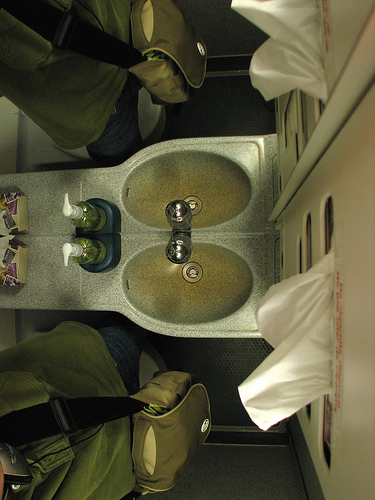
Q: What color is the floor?
A: Black.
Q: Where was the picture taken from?
A: Overhead.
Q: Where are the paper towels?
A: On the wall.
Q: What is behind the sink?
A: A mirror.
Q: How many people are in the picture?
A: 1.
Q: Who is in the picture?
A: A man.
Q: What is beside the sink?
A: Soap bottle.